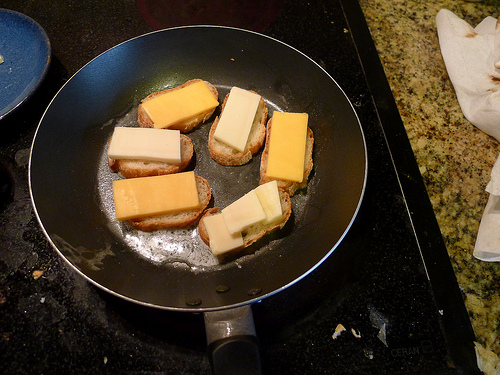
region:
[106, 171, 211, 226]
bread with cheese on it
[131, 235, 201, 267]
butter that is melting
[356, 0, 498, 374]
multicolored counter top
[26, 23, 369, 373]
large pan for cooking on stove top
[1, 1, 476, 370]
black stove top with crumbs on it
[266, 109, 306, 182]
piece of yellow cheese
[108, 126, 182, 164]
piece of white cheese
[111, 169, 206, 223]
The cheese is on the bread.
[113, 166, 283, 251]
The cheese is white and yellow.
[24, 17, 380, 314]
The pan is black.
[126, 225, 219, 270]
Butter is in the pan.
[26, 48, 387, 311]
The pan is made of metal.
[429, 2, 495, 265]
A white towel is by the stove.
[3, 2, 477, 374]
The stove top is black.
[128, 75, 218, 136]
Cheese is being melted on bread.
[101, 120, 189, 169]
Cheese and bread in a pan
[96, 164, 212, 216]
Cheese and bread in a pan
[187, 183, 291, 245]
Cheese and bread in a pan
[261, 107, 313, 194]
Cheese and bread in a pan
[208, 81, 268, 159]
Cheese and bread in a pan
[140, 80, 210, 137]
Cheese and bread in a pan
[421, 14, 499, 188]
cloth on the counter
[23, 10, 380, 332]
Pan on the stove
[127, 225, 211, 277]
melted butter in the pan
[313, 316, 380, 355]
crumbs on the stove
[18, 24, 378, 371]
A frying pan.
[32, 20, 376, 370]
Food in a frying pan.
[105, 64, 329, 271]
Cheese on small slices of bread.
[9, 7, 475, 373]
A pan on a cooking surface.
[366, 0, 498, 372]
A granite counter top.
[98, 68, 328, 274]
White and yellow cheeses on bread.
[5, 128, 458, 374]
Food is spilled around the pan.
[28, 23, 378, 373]
Shallow frying pan on the stove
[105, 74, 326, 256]
Yellow and white cheese on the bread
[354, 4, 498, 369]
Granite countertop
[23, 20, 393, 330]
Black nonstick pan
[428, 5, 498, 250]
White plastic bag on the countertop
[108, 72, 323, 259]
Small oblong bread slices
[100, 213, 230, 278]
Melted butter in the pan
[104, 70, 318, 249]
Cheese over toasts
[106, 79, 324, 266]
White and yellow cheddar cheese pieces on top of bread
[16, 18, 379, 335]
Cooking on the stove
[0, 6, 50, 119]
A round blue plate.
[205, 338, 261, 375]
Black handle on a skillet.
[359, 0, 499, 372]
A marbled counter top.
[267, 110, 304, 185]
piece of cheese over bread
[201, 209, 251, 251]
piece of cheese over bread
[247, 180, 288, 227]
piece of cheese over bread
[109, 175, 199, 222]
piece of cheese over bread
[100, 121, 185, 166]
piece of cheese over bread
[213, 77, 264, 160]
piece of cheese over bread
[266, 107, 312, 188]
piece of cheese over bread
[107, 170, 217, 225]
bread under a piece of cheese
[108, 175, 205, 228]
The cheese is yellow.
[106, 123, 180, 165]
The cheese is white.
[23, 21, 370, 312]
The pan is on the stove.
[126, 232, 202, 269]
There is butter in the pan.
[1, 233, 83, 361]
The stove is dirty.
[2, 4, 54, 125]
The plate is blue.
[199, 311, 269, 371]
The handle of the pan is black.